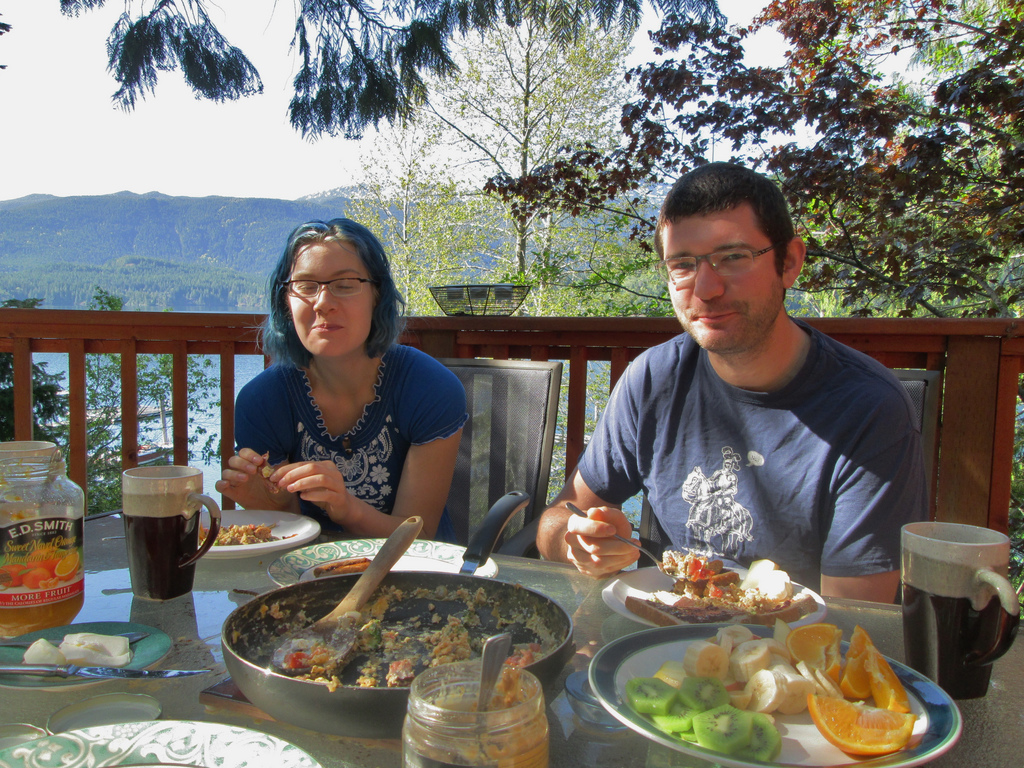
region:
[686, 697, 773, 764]
kiwi on a plate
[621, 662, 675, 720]
kiwi on a plate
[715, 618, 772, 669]
banana on a plate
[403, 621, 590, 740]
jar on a table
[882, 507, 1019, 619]
mug on a table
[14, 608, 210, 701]
plate on a table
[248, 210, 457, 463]
woman sit a table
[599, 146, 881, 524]
man sit at a table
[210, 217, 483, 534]
a person is sitting down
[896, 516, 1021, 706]
a vessel made for drinking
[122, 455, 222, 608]
a vessel made for drinking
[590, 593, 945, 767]
a plate made for dining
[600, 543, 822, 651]
a plate made for dining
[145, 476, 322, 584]
a plate made for dining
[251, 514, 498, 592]
a plate made for dining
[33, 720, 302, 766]
a plate made for dining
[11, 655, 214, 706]
a utensil made for dining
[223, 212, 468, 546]
girl with hair dyed blue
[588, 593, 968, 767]
plate of sliced fruit on table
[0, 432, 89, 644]
jar of orange marmalade on table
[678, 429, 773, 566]
white comic print on man's shirt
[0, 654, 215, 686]
butter knife laid across plate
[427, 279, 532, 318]
black metal woven basket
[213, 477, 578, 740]
dirty frying pan on table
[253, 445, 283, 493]
food in girl's hand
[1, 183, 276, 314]
tree-covered mountain range behind lake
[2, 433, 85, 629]
Jar of orange marmalade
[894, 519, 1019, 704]
Coffee cup in front of man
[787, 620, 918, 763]
Orange slices on plate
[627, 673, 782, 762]
Kiwi slices on plate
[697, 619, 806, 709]
Banana slices on plate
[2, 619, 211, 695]
Plate with butter and butter knife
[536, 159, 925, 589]
Man in blue shirt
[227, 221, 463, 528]
Woman in blue shirt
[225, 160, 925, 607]
Two people having a meal outdoors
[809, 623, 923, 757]
Oranges on a plate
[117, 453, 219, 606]
Mug on the table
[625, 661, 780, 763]
Slices of kiwi on a plate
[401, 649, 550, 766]
Kar of peanut butter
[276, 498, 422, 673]
Wooden spoon in the bowl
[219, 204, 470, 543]
Woman with her eyes closed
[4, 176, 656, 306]
Mountain range in the background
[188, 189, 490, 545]
woman in blue hair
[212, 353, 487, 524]
short sleeve blue shirt with white pattern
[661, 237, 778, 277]
metal glasses frames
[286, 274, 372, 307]
metal glasses frames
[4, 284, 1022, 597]
brown wooden fence behind people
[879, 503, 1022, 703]
white and brown coffee mug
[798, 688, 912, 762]
orange wedge on plate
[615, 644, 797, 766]
cut kiwis on plate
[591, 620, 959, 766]
sliced fruit on plate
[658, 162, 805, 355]
glasses on man's face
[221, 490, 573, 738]
wooden spoon in fryng pan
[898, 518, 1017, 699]
earth tone mug with handle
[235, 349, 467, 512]
shirt with ruffled collar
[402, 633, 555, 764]
utensil in glass jar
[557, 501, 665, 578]
utensil in clenched hand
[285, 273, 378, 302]
closed eyes behind glasses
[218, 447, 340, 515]
fingers of two hands holding food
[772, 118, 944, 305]
leaves on the tree